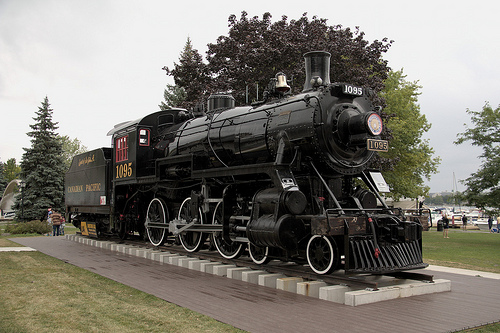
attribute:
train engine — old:
[59, 39, 427, 308]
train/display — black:
[61, 85, 451, 309]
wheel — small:
[311, 232, 342, 291]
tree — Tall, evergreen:
[15, 90, 71, 223]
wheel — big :
[143, 199, 167, 244]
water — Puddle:
[209, 273, 264, 308]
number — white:
[343, 82, 364, 94]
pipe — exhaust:
[296, 42, 336, 93]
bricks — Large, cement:
[323, 284, 455, 309]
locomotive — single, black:
[63, 49, 432, 289]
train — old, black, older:
[61, 48, 427, 277]